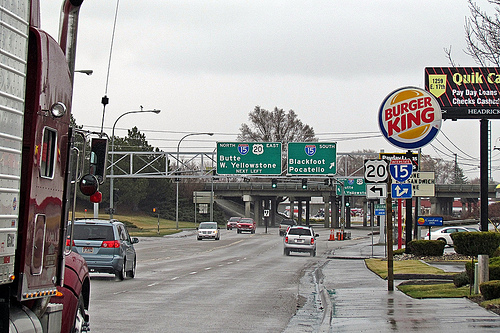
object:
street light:
[173, 132, 217, 229]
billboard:
[423, 68, 499, 120]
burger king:
[380, 95, 435, 137]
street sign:
[214, 140, 282, 177]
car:
[63, 213, 138, 281]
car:
[194, 221, 221, 240]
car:
[280, 224, 319, 258]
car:
[233, 216, 256, 234]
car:
[224, 213, 244, 232]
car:
[423, 226, 470, 249]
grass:
[391, 280, 499, 317]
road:
[87, 222, 377, 332]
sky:
[38, 0, 500, 185]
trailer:
[0, 0, 109, 333]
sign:
[375, 86, 442, 151]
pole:
[403, 152, 413, 250]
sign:
[286, 140, 338, 175]